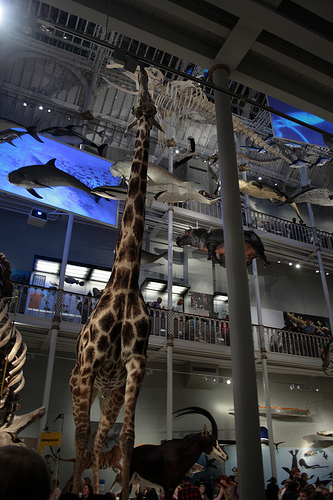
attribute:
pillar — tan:
[208, 64, 265, 499]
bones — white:
[102, 60, 331, 170]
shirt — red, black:
[194, 214, 227, 266]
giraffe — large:
[82, 90, 172, 443]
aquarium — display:
[16, 128, 104, 232]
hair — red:
[216, 474, 233, 489]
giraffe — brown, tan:
[66, 67, 164, 498]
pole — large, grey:
[206, 62, 274, 497]